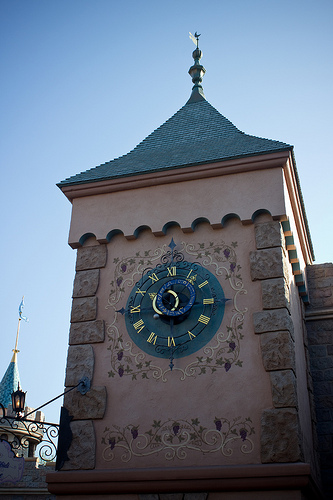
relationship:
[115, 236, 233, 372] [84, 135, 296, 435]
clock on building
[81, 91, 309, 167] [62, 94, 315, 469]
roof on building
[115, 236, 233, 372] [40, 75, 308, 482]
clock on tower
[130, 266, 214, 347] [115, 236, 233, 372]
numeral on clock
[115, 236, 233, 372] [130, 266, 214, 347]
clock has numeral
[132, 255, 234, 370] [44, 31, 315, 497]
clock on tower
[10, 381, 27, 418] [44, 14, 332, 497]
lanter on building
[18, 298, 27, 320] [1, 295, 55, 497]
flag on building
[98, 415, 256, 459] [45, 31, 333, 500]
design on building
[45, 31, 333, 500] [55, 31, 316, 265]
building has roof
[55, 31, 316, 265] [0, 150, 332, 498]
roof on building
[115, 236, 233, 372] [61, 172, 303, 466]
clock on wall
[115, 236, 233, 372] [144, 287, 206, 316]
clock has hands